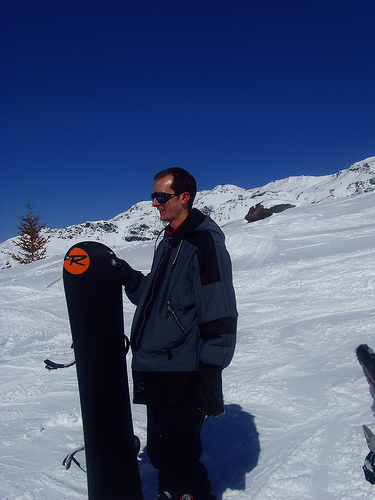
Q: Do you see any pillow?
A: No, there are no pillows.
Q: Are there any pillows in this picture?
A: No, there are no pillows.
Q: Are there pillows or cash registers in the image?
A: No, there are no pillows or cash registers.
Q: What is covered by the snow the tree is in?
A: The ground is covered by the snow.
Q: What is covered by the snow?
A: The ground is covered by the snow.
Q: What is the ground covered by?
A: The ground is covered by the snow.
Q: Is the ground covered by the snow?
A: Yes, the ground is covered by the snow.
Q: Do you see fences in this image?
A: No, there are no fences.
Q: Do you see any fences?
A: No, there are no fences.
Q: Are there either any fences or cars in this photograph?
A: No, there are no fences or cars.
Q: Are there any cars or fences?
A: No, there are no fences or cars.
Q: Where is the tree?
A: The tree is in the snow.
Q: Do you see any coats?
A: Yes, there is a coat.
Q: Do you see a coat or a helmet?
A: Yes, there is a coat.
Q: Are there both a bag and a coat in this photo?
A: No, there is a coat but no bags.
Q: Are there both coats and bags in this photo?
A: No, there is a coat but no bags.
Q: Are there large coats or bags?
A: Yes, there is a large coat.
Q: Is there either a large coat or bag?
A: Yes, there is a large coat.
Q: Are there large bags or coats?
A: Yes, there is a large coat.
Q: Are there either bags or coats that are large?
A: Yes, the coat is large.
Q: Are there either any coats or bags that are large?
A: Yes, the coat is large.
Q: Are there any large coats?
A: Yes, there is a large coat.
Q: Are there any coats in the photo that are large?
A: Yes, there is a coat that is large.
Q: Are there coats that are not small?
A: Yes, there is a large coat.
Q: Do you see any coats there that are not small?
A: Yes, there is a large coat.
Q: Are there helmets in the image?
A: No, there are no helmets.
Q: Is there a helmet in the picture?
A: No, there are no helmets.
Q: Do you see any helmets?
A: No, there are no helmets.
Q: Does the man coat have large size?
A: Yes, the coat is large.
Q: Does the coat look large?
A: Yes, the coat is large.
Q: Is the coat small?
A: No, the coat is large.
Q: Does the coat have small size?
A: No, the coat is large.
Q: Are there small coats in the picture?
A: No, there is a coat but it is large.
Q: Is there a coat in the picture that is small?
A: No, there is a coat but it is large.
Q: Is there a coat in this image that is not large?
A: No, there is a coat but it is large.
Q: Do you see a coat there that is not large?
A: No, there is a coat but it is large.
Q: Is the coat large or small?
A: The coat is large.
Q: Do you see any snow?
A: Yes, there is snow.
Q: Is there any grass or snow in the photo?
A: Yes, there is snow.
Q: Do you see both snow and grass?
A: No, there is snow but no grass.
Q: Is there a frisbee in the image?
A: No, there are no frisbees.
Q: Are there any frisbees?
A: No, there are no frisbees.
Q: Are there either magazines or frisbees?
A: No, there are no frisbees or magazines.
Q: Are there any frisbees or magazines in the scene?
A: No, there are no frisbees or magazines.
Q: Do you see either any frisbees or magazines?
A: No, there are no frisbees or magazines.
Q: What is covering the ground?
A: The snow is covering the ground.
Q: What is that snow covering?
A: The snow is covering the ground.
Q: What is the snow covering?
A: The snow is covering the ground.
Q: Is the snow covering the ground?
A: Yes, the snow is covering the ground.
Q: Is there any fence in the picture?
A: No, there are no fences.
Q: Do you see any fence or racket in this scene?
A: No, there are no fences or rackets.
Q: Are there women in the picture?
A: No, there are no women.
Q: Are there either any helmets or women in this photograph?
A: No, there are no women or helmets.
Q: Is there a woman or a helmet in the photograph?
A: No, there are no women or helmets.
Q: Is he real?
A: Yes, the man is real.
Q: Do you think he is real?
A: Yes, the man is real.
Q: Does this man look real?
A: Yes, the man is real.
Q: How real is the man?
A: The man is real.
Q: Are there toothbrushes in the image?
A: No, there are no toothbrushes.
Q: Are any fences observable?
A: No, there are no fences.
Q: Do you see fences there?
A: No, there are no fences.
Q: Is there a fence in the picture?
A: No, there are no fences.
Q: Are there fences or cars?
A: No, there are no fences or cars.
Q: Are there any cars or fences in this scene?
A: No, there are no fences or cars.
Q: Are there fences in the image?
A: No, there are no fences.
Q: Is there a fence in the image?
A: No, there are no fences.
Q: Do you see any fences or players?
A: No, there are no fences or players.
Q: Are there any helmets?
A: No, there are no helmets.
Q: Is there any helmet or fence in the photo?
A: No, there are no helmets or fences.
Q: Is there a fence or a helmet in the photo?
A: No, there are no helmets or fences.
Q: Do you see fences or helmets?
A: No, there are no helmets or fences.